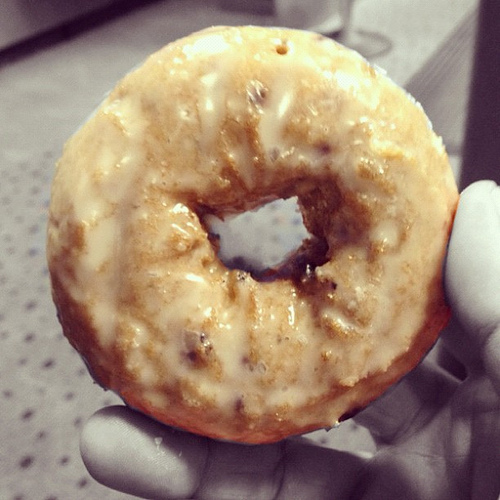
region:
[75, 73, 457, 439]
A brown glazed donut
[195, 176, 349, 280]
Hole in donut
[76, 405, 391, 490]
Persons finger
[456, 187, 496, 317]
Persons thumb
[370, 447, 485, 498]
The persons palm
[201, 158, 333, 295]
Hole in the donut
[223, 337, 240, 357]
Glaze on the donut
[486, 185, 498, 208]
Persons fingernail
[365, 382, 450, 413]
Persons finger holding donut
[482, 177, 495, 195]
Fingernail of person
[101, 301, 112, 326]
this is the color cream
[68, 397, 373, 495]
this is the ring finger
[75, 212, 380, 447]
this is a donut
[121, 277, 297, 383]
this is white icing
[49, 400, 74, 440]
this is the color gray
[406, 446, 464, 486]
this is a palm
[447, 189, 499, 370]
this is a thumb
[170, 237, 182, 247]
this is the color brown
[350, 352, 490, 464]
this is the middle finger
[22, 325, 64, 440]
these are polka dots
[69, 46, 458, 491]
glazed donut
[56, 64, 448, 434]
donut is white and brown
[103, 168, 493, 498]
glazed donut in person's hand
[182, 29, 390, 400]
holes in glazed donut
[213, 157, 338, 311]
hole in center of donut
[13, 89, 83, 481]
floor is black and white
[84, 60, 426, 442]
donut is round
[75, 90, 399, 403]
white glaze on brown donut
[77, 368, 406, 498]
light colored hand holds donut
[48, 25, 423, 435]
donut is round and sugar-coated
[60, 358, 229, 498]
a persons finger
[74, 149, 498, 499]
a hand holding a doughnut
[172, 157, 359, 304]
a hole in the middle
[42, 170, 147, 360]
icing on a doughnut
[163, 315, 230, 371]
dough bubbling up on the doughnut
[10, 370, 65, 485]
a table behind the doughnut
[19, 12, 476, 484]
a glazed cake doughnut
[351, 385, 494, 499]
a persons palm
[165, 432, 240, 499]
crease of a persons finger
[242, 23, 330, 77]
a hole in the side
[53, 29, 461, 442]
the person holds a donut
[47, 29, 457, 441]
the donut has icing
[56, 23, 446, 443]
the hand holds donut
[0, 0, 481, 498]
the counter has dots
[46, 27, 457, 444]
the donut is large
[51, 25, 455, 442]
the donut is big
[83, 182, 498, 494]
the hand is big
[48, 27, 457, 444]
the donut has a lot of icing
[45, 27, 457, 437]
the snack has icing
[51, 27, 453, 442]
the donut is round